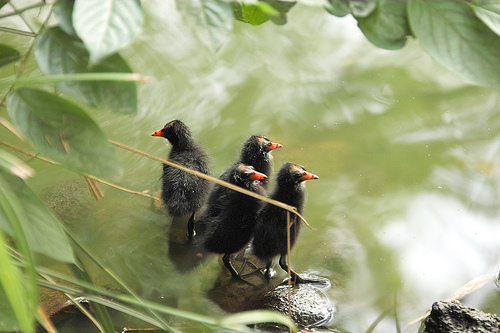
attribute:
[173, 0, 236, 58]
leaf — green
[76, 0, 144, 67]
leaf — green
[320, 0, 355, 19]
leaf — green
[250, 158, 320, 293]
bird — small, black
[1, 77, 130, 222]
leaf — green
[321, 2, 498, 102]
leaf — green